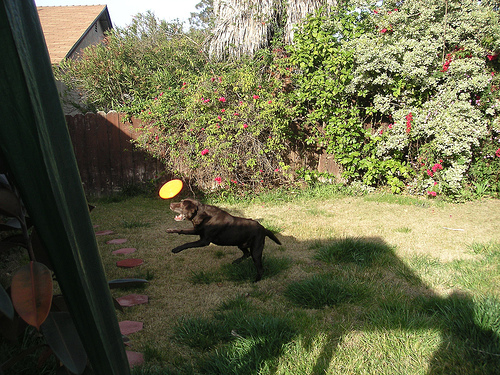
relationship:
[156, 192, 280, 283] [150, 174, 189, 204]
dog grabbing frisbee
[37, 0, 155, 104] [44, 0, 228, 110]
building in background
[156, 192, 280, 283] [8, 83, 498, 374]
dog in back yard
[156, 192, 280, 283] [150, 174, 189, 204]
dog has frisbee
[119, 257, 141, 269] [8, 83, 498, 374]
frisbee on back yard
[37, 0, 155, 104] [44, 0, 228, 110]
house in background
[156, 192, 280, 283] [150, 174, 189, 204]
dog chasing frisbee